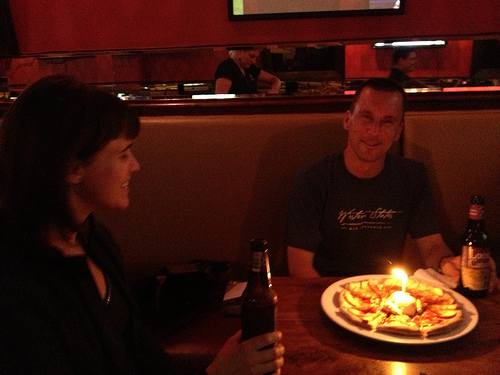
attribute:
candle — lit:
[402, 280, 405, 298]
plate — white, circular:
[320, 273, 480, 345]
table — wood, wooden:
[164, 275, 498, 374]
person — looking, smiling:
[285, 77, 496, 295]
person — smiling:
[0, 73, 286, 374]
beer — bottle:
[459, 193, 490, 298]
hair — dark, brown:
[1, 72, 141, 264]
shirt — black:
[0, 215, 211, 374]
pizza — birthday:
[339, 278, 463, 336]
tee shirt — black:
[285, 149, 442, 276]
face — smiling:
[115, 142, 142, 211]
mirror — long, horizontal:
[226, 0, 405, 22]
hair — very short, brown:
[349, 76, 405, 124]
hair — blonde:
[228, 47, 264, 59]